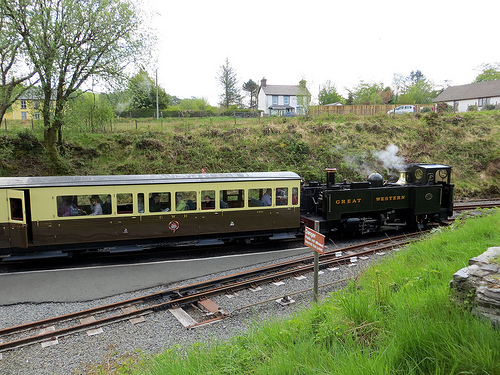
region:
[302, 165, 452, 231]
a black train engine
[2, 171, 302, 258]
a yellow and brown passenger car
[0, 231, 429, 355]
a set of train tracks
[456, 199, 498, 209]
a set of train tracks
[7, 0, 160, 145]
large green tree in distance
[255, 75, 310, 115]
a house in distance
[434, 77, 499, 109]
a house in distance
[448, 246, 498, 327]
a large white rock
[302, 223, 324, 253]
a red and white sign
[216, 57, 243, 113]
large green tree in distance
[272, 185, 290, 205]
window on side of train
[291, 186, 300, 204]
window on side of train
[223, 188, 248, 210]
window on side of train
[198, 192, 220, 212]
window on side of train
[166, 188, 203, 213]
window on side of train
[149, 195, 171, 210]
window on side of train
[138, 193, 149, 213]
window on side of train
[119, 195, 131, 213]
window on side of train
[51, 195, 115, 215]
window on side of train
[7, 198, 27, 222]
window on side of train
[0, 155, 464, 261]
a small passenger train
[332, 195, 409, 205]
a Great Western sign on the side of the train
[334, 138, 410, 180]
smoke coming out of the front of the train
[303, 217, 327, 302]
a small red sign next to the train tracks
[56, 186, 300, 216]
passengers inside of the train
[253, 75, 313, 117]
a white house with a gray roof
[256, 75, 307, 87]
two chimneys on the gray roof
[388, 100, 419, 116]
a silver hatchback car parked near the house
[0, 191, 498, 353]
a set of train tracks on the gravel road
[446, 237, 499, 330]
a pile of stones in the grass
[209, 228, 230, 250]
part of a train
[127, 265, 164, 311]
part of a floor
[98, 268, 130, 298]
part of a florr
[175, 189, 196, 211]
part of a window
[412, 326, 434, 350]
part of a grass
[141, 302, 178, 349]
part of a ground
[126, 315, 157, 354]
part of a grpound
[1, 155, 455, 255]
a small train on the tracks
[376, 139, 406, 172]
steam coming from the train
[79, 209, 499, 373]
grass in front of the train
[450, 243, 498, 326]
a large rock in front of the train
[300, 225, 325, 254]
a brown sign in front of the train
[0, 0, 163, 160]
trees behind the train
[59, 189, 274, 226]
people sitting on the train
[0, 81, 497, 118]
buildings behind the train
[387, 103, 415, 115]
a car parked behind the train